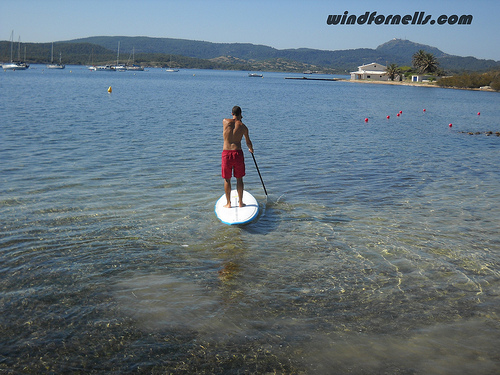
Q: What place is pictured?
A: It is an ocean.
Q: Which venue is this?
A: This is an ocean.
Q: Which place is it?
A: It is an ocean.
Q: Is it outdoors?
A: Yes, it is outdoors.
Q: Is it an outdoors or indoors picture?
A: It is outdoors.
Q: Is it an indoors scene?
A: No, it is outdoors.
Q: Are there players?
A: No, there are no players.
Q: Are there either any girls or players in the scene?
A: No, there are no players or girls.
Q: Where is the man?
A: The man is in the water.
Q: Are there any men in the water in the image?
A: Yes, there is a man in the water.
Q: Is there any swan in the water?
A: No, there is a man in the water.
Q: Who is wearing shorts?
A: The man is wearing shorts.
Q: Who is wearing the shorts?
A: The man is wearing shorts.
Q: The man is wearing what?
A: The man is wearing shorts.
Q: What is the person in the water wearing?
A: The man is wearing shorts.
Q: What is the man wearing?
A: The man is wearing shorts.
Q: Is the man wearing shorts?
A: Yes, the man is wearing shorts.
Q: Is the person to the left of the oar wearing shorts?
A: Yes, the man is wearing shorts.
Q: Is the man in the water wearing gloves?
A: No, the man is wearing shorts.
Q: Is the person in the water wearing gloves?
A: No, the man is wearing shorts.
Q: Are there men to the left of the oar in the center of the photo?
A: Yes, there is a man to the left of the oar.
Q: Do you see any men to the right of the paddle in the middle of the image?
A: No, the man is to the left of the oar.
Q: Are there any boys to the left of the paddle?
A: No, there is a man to the left of the paddle.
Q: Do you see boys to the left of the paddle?
A: No, there is a man to the left of the paddle.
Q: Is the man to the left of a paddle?
A: Yes, the man is to the left of a paddle.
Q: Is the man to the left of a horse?
A: No, the man is to the left of a paddle.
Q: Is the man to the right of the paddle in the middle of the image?
A: No, the man is to the left of the oar.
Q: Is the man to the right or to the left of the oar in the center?
A: The man is to the left of the paddle.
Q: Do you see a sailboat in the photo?
A: Yes, there is a sailboat.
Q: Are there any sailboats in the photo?
A: Yes, there is a sailboat.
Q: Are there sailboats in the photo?
A: Yes, there is a sailboat.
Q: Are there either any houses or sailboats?
A: Yes, there is a sailboat.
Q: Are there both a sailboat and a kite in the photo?
A: No, there is a sailboat but no kites.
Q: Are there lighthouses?
A: No, there are no lighthouses.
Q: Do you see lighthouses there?
A: No, there are no lighthouses.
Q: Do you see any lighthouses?
A: No, there are no lighthouses.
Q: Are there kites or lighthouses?
A: No, there are no lighthouses or kites.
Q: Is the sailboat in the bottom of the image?
A: No, the sailboat is in the top of the image.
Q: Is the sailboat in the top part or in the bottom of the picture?
A: The sailboat is in the top of the image.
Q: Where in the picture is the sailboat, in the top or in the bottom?
A: The sailboat is in the top of the image.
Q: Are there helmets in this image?
A: No, there are no helmets.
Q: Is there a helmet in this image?
A: No, there are no helmets.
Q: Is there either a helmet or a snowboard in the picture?
A: No, there are no helmets or snowboards.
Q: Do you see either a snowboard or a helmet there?
A: No, there are no helmets or snowboards.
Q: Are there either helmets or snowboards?
A: No, there are no helmets or snowboards.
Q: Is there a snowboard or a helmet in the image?
A: No, there are no helmets or snowboards.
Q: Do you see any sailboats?
A: Yes, there is a sailboat.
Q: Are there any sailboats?
A: Yes, there is a sailboat.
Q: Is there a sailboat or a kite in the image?
A: Yes, there is a sailboat.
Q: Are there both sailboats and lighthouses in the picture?
A: No, there is a sailboat but no lighthouses.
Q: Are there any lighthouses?
A: No, there are no lighthouses.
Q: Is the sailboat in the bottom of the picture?
A: No, the sailboat is in the top of the image.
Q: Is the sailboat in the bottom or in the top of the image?
A: The sailboat is in the top of the image.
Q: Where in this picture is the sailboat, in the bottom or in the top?
A: The sailboat is in the top of the image.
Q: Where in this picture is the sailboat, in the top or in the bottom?
A: The sailboat is in the top of the image.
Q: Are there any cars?
A: No, there are no cars.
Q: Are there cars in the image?
A: No, there are no cars.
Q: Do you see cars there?
A: No, there are no cars.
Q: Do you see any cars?
A: No, there are no cars.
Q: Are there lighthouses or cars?
A: No, there are no cars or lighthouses.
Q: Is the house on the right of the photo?
A: Yes, the house is on the right of the image.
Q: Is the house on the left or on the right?
A: The house is on the right of the image.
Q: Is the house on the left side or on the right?
A: The house is on the right of the image.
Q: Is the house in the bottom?
A: No, the house is in the top of the image.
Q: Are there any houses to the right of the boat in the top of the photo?
A: Yes, there is a house to the right of the boat.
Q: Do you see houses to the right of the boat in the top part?
A: Yes, there is a house to the right of the boat.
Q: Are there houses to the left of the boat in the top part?
A: No, the house is to the right of the boat.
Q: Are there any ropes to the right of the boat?
A: No, there is a house to the right of the boat.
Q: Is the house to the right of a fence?
A: No, the house is to the right of a boat.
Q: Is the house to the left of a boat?
A: No, the house is to the right of a boat.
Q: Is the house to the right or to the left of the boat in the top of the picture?
A: The house is to the right of the boat.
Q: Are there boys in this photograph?
A: No, there are no boys.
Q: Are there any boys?
A: No, there are no boys.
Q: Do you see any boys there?
A: No, there are no boys.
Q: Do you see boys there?
A: No, there are no boys.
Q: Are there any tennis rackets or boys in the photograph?
A: No, there are no boys or tennis rackets.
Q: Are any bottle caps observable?
A: No, there are no bottle caps.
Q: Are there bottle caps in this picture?
A: No, there are no bottle caps.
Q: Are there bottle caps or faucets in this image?
A: No, there are no bottle caps or faucets.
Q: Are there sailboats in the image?
A: Yes, there is a sailboat.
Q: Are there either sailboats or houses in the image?
A: Yes, there is a sailboat.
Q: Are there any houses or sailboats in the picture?
A: Yes, there is a sailboat.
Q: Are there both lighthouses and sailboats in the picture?
A: No, there is a sailboat but no lighthouses.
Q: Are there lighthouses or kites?
A: No, there are no lighthouses or kites.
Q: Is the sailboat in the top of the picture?
A: Yes, the sailboat is in the top of the image.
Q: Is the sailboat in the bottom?
A: No, the sailboat is in the top of the image.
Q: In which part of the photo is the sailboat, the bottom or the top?
A: The sailboat is in the top of the image.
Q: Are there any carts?
A: No, there are no carts.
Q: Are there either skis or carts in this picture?
A: No, there are no carts or skis.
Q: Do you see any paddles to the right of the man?
A: Yes, there is a paddle to the right of the man.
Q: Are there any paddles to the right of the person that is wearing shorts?
A: Yes, there is a paddle to the right of the man.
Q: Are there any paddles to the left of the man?
A: No, the paddle is to the right of the man.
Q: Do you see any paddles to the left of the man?
A: No, the paddle is to the right of the man.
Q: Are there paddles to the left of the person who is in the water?
A: No, the paddle is to the right of the man.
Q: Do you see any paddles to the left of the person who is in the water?
A: No, the paddle is to the right of the man.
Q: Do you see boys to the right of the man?
A: No, there is a paddle to the right of the man.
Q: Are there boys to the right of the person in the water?
A: No, there is a paddle to the right of the man.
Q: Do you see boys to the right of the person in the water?
A: No, there is a paddle to the right of the man.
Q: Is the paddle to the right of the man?
A: Yes, the paddle is to the right of the man.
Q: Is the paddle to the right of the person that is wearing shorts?
A: Yes, the paddle is to the right of the man.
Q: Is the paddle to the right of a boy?
A: No, the paddle is to the right of the man.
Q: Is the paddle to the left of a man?
A: No, the paddle is to the right of a man.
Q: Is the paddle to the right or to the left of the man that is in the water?
A: The paddle is to the right of the man.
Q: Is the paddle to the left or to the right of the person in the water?
A: The paddle is to the right of the man.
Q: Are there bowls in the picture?
A: No, there are no bowls.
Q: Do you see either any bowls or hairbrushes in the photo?
A: No, there are no bowls or hairbrushes.